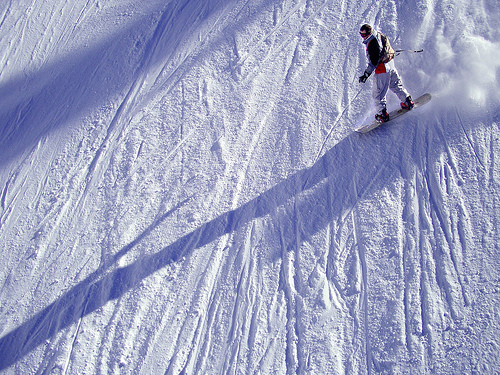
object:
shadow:
[0, 108, 418, 374]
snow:
[1, 2, 499, 375]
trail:
[397, 118, 430, 373]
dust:
[416, 34, 500, 125]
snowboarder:
[358, 24, 414, 123]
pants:
[374, 71, 409, 115]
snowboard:
[355, 92, 433, 134]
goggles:
[359, 32, 370, 38]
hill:
[1, 1, 499, 374]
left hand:
[359, 71, 371, 83]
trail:
[319, 137, 366, 374]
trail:
[273, 190, 309, 374]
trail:
[220, 127, 253, 375]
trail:
[0, 1, 35, 87]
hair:
[360, 24, 372, 34]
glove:
[359, 75, 368, 83]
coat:
[362, 30, 397, 74]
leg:
[373, 78, 389, 113]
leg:
[388, 73, 410, 100]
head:
[359, 24, 372, 39]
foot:
[375, 112, 389, 123]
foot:
[400, 99, 413, 111]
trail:
[355, 1, 435, 132]